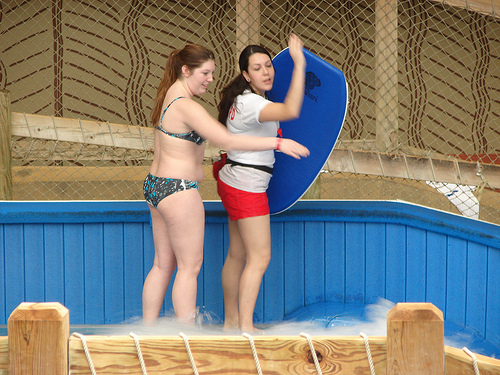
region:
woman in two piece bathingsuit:
[140, 37, 314, 339]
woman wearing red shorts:
[212, 28, 353, 340]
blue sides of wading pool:
[1, 193, 496, 364]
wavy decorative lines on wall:
[108, 1, 160, 128]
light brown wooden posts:
[382, 287, 454, 374]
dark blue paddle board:
[262, 40, 353, 221]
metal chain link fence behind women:
[2, 3, 497, 224]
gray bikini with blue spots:
[140, 95, 205, 206]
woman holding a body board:
[212, 31, 348, 334]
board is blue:
[256, 45, 346, 215]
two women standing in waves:
[135, 30, 347, 335]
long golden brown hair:
[150, 40, 215, 128]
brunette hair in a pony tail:
[213, 42, 269, 127]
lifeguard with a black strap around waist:
[210, 32, 310, 328]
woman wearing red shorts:
[212, 30, 307, 333]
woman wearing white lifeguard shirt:
[210, 34, 308, 331]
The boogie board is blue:
[220, 43, 350, 218]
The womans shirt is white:
[219, 95, 281, 193]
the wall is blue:
[3, 198, 498, 357]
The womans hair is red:
[149, 44, 220, 134]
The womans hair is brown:
[218, 42, 275, 132]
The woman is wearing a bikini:
[143, 39, 208, 333]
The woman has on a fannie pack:
[210, 150, 275, 191]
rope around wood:
[66, 331, 383, 369]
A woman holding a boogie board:
[217, 34, 352, 330]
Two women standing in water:
[137, 27, 304, 353]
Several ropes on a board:
[81, 326, 379, 366]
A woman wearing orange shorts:
[212, 35, 302, 362]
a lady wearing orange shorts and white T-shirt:
[218, 27, 294, 345]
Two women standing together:
[123, 30, 315, 330]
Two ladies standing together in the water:
[139, 28, 290, 333]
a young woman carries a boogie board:
[215, 32, 346, 347]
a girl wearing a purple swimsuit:
[137, 43, 218, 327]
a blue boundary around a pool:
[2, 193, 494, 340]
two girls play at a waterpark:
[137, 35, 352, 330]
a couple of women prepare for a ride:
[136, 33, 356, 344]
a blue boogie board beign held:
[262, 43, 353, 223]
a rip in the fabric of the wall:
[412, 155, 497, 226]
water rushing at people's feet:
[55, 283, 443, 350]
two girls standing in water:
[136, 37, 306, 326]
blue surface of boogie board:
[249, 44, 348, 216]